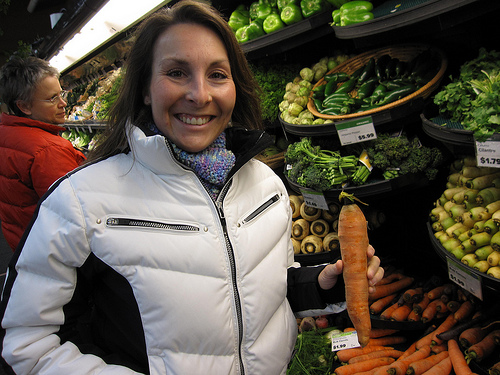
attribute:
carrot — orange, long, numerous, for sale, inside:
[336, 189, 374, 351]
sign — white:
[333, 114, 378, 147]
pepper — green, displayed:
[322, 95, 357, 105]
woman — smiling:
[0, 0, 387, 374]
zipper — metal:
[240, 193, 281, 227]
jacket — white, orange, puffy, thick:
[0, 119, 351, 374]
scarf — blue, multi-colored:
[166, 127, 237, 188]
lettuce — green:
[263, 68, 287, 98]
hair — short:
[85, 0, 266, 161]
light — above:
[52, 0, 167, 75]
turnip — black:
[301, 236, 324, 259]